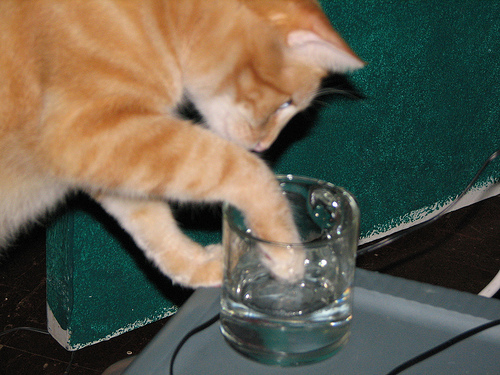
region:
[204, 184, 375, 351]
a clear drinking glass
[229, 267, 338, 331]
shallow water in a glass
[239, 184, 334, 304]
a cat's paw in the glass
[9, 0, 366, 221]
an orange tabby cat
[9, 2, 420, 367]
a cat sticking its paw in a glass of water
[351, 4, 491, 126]
green painted wallpaper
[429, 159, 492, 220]
a gray power cord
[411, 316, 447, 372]
a black power cord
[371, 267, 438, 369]
a gray rubber storage lid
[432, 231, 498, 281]
a dark brown tiled floor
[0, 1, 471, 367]
The cat is putting his paw in the glass.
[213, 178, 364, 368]
The glass is clear.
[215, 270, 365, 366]
The glass is partially filled with water.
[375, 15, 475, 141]
The wall is green.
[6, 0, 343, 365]
The cat is orange.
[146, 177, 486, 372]
The glass is on top of a gre box.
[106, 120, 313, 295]
The cat has two front legs.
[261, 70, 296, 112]
The cat has an eye.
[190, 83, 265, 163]
The cat has whiskers.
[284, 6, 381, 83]
The cat has an ear.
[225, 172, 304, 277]
hand in the cup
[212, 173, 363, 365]
the glass on the tub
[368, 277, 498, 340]
the lid of a tub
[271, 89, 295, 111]
the eye of the cat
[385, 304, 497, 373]
chord on the tub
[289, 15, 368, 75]
ear of the cat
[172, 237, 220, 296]
paw on the lid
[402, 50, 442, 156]
green paint .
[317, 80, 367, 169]
the shaodw of the cats ear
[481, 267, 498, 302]
Part of a white chord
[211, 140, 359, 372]
a glass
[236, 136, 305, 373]
a glass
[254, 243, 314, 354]
a glass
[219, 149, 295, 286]
a glass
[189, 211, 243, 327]
a glass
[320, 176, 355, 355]
a glass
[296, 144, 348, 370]
a glass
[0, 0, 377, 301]
the cat is yellow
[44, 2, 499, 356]
the wall is green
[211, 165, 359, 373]
the water is in the glass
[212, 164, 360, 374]
the glass is clear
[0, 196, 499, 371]
the floor is black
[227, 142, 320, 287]
the cat's paw is in the glass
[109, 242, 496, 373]
the glass is on the plastic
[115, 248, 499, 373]
the plastic is grey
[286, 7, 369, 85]
the cat's ear is pointy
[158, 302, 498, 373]
the cord is black